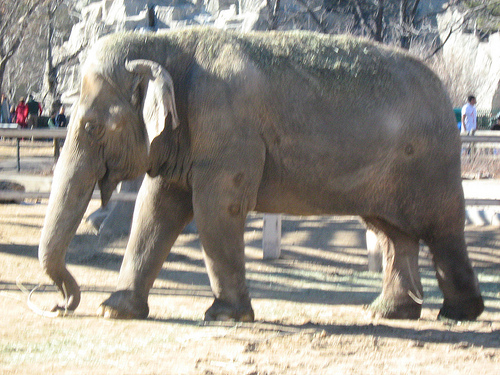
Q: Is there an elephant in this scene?
A: Yes, there is an elephant.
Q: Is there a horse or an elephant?
A: Yes, there is an elephant.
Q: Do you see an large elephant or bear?
A: Yes, there is a large elephant.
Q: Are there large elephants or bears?
A: Yes, there is a large elephant.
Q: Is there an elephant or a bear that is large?
A: Yes, the elephant is large.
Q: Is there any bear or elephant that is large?
A: Yes, the elephant is large.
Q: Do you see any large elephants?
A: Yes, there is a large elephant.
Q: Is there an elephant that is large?
A: Yes, there is an elephant that is large.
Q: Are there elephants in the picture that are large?
A: Yes, there is an elephant that is large.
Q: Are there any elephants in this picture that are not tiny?
A: Yes, there is a large elephant.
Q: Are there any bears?
A: No, there are no bears.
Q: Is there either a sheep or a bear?
A: No, there are no bears or sheep.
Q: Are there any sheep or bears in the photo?
A: No, there are no bears or sheep.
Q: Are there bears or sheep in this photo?
A: No, there are no bears or sheep.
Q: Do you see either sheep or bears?
A: No, there are no bears or sheep.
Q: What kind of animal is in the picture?
A: The animal is an elephant.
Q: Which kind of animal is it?
A: The animal is an elephant.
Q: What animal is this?
A: This is an elephant.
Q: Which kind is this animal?
A: This is an elephant.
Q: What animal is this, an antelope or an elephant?
A: This is an elephant.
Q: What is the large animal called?
A: The animal is an elephant.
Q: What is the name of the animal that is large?
A: The animal is an elephant.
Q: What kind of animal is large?
A: The animal is an elephant.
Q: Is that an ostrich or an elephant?
A: That is an elephant.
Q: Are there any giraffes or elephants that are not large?
A: No, there is an elephant but it is large.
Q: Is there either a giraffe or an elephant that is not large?
A: No, there is an elephant but it is large.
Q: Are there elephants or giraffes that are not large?
A: No, there is an elephant but it is large.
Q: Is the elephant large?
A: Yes, the elephant is large.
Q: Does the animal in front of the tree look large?
A: Yes, the elephant is large.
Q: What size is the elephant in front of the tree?
A: The elephant is large.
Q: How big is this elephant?
A: The elephant is large.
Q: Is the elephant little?
A: No, the elephant is large.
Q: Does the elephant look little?
A: No, the elephant is large.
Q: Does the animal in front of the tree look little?
A: No, the elephant is large.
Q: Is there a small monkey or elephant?
A: No, there is an elephant but it is large.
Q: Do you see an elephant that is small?
A: No, there is an elephant but it is large.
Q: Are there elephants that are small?
A: No, there is an elephant but it is large.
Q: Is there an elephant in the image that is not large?
A: No, there is an elephant but it is large.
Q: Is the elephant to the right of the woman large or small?
A: The elephant is large.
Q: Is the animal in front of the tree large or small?
A: The elephant is large.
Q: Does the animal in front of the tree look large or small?
A: The elephant is large.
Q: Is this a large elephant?
A: Yes, this is a large elephant.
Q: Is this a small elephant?
A: No, this is a large elephant.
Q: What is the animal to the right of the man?
A: The animal is an elephant.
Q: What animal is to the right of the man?
A: The animal is an elephant.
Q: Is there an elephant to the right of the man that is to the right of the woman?
A: Yes, there is an elephant to the right of the man.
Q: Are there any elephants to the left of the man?
A: No, the elephant is to the right of the man.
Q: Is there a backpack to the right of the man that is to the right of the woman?
A: No, there is an elephant to the right of the man.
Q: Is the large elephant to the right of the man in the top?
A: Yes, the elephant is to the right of the man.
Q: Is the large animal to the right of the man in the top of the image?
A: Yes, the elephant is to the right of the man.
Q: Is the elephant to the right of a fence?
A: No, the elephant is to the right of the man.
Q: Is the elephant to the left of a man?
A: No, the elephant is to the right of a man.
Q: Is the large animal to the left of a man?
A: No, the elephant is to the right of a man.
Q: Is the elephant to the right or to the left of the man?
A: The elephant is to the right of the man.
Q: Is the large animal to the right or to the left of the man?
A: The elephant is to the right of the man.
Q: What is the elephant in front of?
A: The elephant is in front of the tree.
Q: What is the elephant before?
A: The elephant is in front of the tree.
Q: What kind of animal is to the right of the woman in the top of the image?
A: The animal is an elephant.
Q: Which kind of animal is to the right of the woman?
A: The animal is an elephant.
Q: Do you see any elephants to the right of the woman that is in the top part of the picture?
A: Yes, there is an elephant to the right of the woman.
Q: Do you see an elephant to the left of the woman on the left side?
A: No, the elephant is to the right of the woman.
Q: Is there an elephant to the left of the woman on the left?
A: No, the elephant is to the right of the woman.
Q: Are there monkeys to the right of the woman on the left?
A: No, there is an elephant to the right of the woman.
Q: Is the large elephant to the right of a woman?
A: Yes, the elephant is to the right of a woman.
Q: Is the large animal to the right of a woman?
A: Yes, the elephant is to the right of a woman.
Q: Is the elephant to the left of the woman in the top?
A: No, the elephant is to the right of the woman.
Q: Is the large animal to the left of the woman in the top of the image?
A: No, the elephant is to the right of the woman.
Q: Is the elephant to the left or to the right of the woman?
A: The elephant is to the right of the woman.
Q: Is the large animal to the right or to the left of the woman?
A: The elephant is to the right of the woman.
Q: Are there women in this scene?
A: Yes, there is a woman.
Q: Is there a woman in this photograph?
A: Yes, there is a woman.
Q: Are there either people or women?
A: Yes, there is a woman.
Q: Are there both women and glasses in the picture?
A: No, there is a woman but no glasses.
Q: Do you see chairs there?
A: No, there are no chairs.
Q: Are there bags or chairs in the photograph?
A: No, there are no chairs or bags.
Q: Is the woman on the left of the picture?
A: Yes, the woman is on the left of the image.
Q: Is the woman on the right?
A: No, the woman is on the left of the image.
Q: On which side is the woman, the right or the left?
A: The woman is on the left of the image.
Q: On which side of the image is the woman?
A: The woman is on the left of the image.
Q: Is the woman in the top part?
A: Yes, the woman is in the top of the image.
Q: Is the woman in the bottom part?
A: No, the woman is in the top of the image.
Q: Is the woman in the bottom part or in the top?
A: The woman is in the top of the image.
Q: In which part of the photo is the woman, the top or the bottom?
A: The woman is in the top of the image.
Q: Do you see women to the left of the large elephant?
A: Yes, there is a woman to the left of the elephant.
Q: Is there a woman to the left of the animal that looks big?
A: Yes, there is a woman to the left of the elephant.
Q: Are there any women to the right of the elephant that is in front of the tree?
A: No, the woman is to the left of the elephant.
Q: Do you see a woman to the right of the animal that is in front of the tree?
A: No, the woman is to the left of the elephant.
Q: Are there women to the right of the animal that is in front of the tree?
A: No, the woman is to the left of the elephant.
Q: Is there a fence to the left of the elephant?
A: No, there is a woman to the left of the elephant.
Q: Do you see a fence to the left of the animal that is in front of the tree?
A: No, there is a woman to the left of the elephant.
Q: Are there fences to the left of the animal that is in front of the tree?
A: No, there is a woman to the left of the elephant.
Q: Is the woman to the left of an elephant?
A: Yes, the woman is to the left of an elephant.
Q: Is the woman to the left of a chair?
A: No, the woman is to the left of an elephant.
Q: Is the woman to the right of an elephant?
A: No, the woman is to the left of an elephant.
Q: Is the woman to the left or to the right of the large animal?
A: The woman is to the left of the elephant.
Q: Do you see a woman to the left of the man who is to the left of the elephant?
A: Yes, there is a woman to the left of the man.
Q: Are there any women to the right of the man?
A: No, the woman is to the left of the man.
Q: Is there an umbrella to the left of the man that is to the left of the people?
A: No, there is a woman to the left of the man.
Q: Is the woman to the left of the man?
A: Yes, the woman is to the left of the man.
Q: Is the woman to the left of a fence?
A: No, the woman is to the left of the man.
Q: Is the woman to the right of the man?
A: No, the woman is to the left of the man.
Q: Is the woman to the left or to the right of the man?
A: The woman is to the left of the man.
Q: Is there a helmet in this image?
A: No, there are no helmets.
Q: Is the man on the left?
A: Yes, the man is on the left of the image.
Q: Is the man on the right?
A: No, the man is on the left of the image.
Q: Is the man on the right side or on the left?
A: The man is on the left of the image.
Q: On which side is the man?
A: The man is on the left of the image.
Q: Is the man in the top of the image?
A: Yes, the man is in the top of the image.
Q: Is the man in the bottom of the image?
A: No, the man is in the top of the image.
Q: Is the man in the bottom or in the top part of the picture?
A: The man is in the top of the image.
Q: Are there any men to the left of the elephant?
A: Yes, there is a man to the left of the elephant.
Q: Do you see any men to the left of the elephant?
A: Yes, there is a man to the left of the elephant.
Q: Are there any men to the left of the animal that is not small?
A: Yes, there is a man to the left of the elephant.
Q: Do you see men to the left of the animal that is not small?
A: Yes, there is a man to the left of the elephant.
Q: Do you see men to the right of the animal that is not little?
A: No, the man is to the left of the elephant.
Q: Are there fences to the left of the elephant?
A: No, there is a man to the left of the elephant.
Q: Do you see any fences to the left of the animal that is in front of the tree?
A: No, there is a man to the left of the elephant.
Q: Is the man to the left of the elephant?
A: Yes, the man is to the left of the elephant.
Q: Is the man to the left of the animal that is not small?
A: Yes, the man is to the left of the elephant.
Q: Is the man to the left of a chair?
A: No, the man is to the left of the elephant.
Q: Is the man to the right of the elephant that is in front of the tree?
A: No, the man is to the left of the elephant.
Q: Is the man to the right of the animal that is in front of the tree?
A: No, the man is to the left of the elephant.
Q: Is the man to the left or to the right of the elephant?
A: The man is to the left of the elephant.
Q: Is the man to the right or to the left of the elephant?
A: The man is to the left of the elephant.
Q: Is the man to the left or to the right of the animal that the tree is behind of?
A: The man is to the left of the elephant.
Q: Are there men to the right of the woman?
A: Yes, there is a man to the right of the woman.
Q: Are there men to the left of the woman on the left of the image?
A: No, the man is to the right of the woman.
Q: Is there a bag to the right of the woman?
A: No, there is a man to the right of the woman.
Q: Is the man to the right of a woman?
A: Yes, the man is to the right of a woman.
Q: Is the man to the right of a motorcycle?
A: No, the man is to the right of a woman.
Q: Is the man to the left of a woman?
A: No, the man is to the right of a woman.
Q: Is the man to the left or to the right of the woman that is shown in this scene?
A: The man is to the right of the woman.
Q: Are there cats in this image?
A: No, there are no cats.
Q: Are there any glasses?
A: No, there are no glasses.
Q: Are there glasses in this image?
A: No, there are no glasses.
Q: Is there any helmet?
A: No, there are no helmets.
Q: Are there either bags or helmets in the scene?
A: No, there are no helmets or bags.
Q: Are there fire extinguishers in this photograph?
A: No, there are no fire extinguishers.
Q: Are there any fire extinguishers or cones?
A: No, there are no fire extinguishers or cones.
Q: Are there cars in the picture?
A: No, there are no cars.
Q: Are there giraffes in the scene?
A: No, there are no giraffes.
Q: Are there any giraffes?
A: No, there are no giraffes.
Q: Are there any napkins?
A: No, there are no napkins.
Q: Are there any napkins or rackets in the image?
A: No, there are no napkins or rackets.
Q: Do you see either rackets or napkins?
A: No, there are no napkins or rackets.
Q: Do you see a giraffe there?
A: No, there are no giraffes.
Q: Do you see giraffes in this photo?
A: No, there are no giraffes.